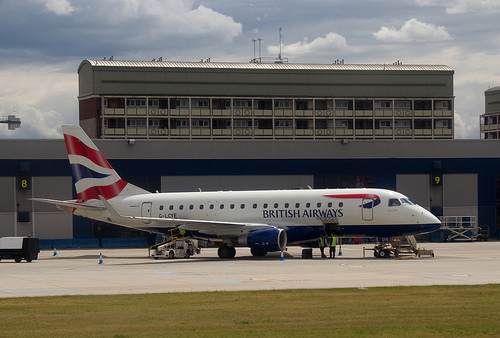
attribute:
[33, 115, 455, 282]
plane — white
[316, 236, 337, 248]
vest — green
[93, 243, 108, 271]
cone — blue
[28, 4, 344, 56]
sky — cloudy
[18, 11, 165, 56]
clouds — gray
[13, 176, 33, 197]
number — yellow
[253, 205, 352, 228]
text — blue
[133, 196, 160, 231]
door — white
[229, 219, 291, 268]
engine — blue